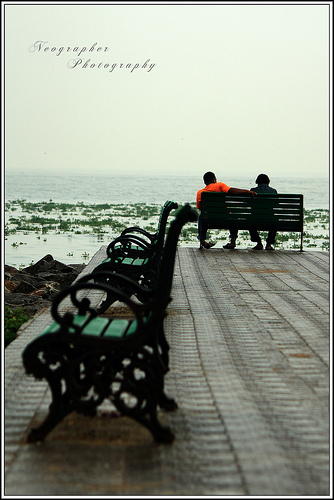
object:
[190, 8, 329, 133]
sky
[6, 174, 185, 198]
ocean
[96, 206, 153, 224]
grass patches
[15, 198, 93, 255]
beach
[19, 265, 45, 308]
rocks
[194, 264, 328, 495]
boardwalk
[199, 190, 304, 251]
bench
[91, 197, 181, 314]
benches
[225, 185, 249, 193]
man's arm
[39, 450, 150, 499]
shadow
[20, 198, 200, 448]
bench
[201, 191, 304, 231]
back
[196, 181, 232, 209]
orange shirt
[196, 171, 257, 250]
man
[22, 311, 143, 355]
seat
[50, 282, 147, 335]
curved arm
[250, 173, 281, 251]
woman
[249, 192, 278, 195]
gray top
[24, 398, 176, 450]
cement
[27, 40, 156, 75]
copyright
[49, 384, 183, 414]
legs